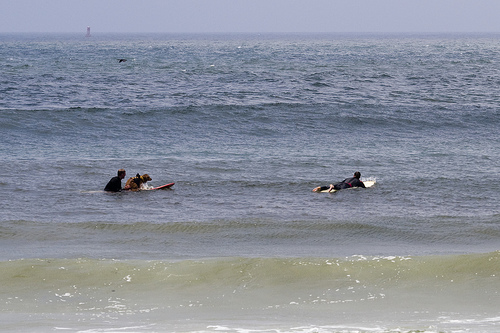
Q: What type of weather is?
A: It is cloudless.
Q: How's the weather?
A: It is cloudless.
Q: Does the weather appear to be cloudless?
A: Yes, it is cloudless.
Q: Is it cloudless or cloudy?
A: It is cloudless.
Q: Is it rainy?
A: No, it is cloudless.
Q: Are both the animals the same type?
A: No, they are birds and dogs.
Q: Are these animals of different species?
A: Yes, they are birds and dogs.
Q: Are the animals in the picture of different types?
A: Yes, they are birds and dogs.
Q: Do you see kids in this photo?
A: No, there are no kids.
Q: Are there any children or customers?
A: No, there are no children or customers.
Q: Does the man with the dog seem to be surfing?
A: Yes, the man is surfing.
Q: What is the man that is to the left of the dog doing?
A: The man is surfing.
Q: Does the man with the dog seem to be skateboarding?
A: No, the man is surfing.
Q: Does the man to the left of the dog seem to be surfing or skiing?
A: The man is surfing.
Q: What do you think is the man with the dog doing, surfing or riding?
A: The man is surfing.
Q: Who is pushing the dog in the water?
A: The man is pushing the dog.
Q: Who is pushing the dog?
A: The man is pushing the dog.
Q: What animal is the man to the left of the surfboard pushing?
A: The man is pushing the dog.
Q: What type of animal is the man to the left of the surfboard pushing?
A: The man is pushing the dog.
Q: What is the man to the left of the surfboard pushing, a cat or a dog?
A: The man is pushing a dog.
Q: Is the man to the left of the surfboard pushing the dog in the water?
A: Yes, the man is pushing the dog.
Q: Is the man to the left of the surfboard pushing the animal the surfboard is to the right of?
A: Yes, the man is pushing the dog.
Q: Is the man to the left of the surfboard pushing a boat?
A: No, the man is pushing the dog.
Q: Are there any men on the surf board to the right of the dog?
A: Yes, there is a man on the surfboard.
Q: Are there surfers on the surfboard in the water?
A: No, there is a man on the surfboard.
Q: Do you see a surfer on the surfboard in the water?
A: No, there is a man on the surfboard.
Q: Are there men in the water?
A: Yes, there is a man in the water.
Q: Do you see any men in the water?
A: Yes, there is a man in the water.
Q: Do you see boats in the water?
A: No, there is a man in the water.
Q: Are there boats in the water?
A: No, there is a man in the water.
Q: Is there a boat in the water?
A: No, there is a man in the water.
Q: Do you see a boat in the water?
A: No, there is a man in the water.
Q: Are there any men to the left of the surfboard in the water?
A: Yes, there is a man to the left of the surfboard.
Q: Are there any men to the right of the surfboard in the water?
A: No, the man is to the left of the surfboard.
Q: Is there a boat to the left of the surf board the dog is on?
A: No, there is a man to the left of the surfboard.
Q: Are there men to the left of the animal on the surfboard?
A: Yes, there is a man to the left of the dog.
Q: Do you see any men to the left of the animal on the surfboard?
A: Yes, there is a man to the left of the dog.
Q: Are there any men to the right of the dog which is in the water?
A: No, the man is to the left of the dog.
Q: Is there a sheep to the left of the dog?
A: No, there is a man to the left of the dog.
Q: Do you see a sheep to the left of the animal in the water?
A: No, there is a man to the left of the dog.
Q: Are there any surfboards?
A: Yes, there is a surfboard.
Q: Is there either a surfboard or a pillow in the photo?
A: Yes, there is a surfboard.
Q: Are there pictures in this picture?
A: No, there are no pictures.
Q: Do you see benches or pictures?
A: No, there are no pictures or benches.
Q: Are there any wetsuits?
A: Yes, there is a wetsuit.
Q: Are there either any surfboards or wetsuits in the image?
A: Yes, there is a wetsuit.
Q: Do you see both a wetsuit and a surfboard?
A: Yes, there are both a wetsuit and a surfboard.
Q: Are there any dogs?
A: Yes, there is a dog.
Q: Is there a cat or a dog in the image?
A: Yes, there is a dog.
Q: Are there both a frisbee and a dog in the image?
A: No, there is a dog but no frisbees.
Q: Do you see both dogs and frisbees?
A: No, there is a dog but no frisbees.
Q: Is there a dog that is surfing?
A: Yes, there is a dog that is surfing.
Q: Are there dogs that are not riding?
A: Yes, there is a dog that is surfing.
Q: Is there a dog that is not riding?
A: Yes, there is a dog that is surfing.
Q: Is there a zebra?
A: No, there are no zebras.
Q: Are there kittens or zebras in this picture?
A: No, there are no zebras or kittens.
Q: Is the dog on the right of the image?
A: No, the dog is on the left of the image.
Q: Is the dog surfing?
A: Yes, the dog is surfing.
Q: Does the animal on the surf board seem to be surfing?
A: Yes, the dog is surfing.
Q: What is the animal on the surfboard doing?
A: The dog is surfing.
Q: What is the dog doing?
A: The dog is surfing.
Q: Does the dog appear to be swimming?
A: No, the dog is surfing.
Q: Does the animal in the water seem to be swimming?
A: No, the dog is surfing.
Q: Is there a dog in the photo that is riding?
A: No, there is a dog but it is surfing.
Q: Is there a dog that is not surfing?
A: No, there is a dog but it is surfing.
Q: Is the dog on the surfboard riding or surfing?
A: The dog is surfing.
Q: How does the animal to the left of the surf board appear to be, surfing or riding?
A: The dog is surfing.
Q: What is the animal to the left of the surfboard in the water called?
A: The animal is a dog.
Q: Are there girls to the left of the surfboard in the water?
A: No, there is a dog to the left of the surfboard.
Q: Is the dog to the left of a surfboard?
A: Yes, the dog is to the left of a surfboard.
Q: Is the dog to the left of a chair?
A: No, the dog is to the left of a surfboard.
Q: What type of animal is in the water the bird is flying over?
A: The animal is a dog.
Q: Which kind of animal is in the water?
A: The animal is a dog.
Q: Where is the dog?
A: The dog is in the water.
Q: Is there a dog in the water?
A: Yes, there is a dog in the water.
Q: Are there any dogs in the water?
A: Yes, there is a dog in the water.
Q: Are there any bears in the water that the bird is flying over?
A: No, there is a dog in the water.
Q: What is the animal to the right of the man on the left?
A: The animal is a dog.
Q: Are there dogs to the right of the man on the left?
A: Yes, there is a dog to the right of the man.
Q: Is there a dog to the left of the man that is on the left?
A: No, the dog is to the right of the man.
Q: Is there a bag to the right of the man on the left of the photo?
A: No, there is a dog to the right of the man.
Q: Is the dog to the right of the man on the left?
A: Yes, the dog is to the right of the man.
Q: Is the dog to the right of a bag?
A: No, the dog is to the right of the man.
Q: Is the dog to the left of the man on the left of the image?
A: No, the dog is to the right of the man.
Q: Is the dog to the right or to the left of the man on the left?
A: The dog is to the right of the man.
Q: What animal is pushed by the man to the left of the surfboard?
A: The dog is pushed by the man.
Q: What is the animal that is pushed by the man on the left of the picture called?
A: The animal is a dog.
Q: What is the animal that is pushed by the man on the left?
A: The animal is a dog.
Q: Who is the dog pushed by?
A: The dog is pushed by the man.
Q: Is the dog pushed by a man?
A: Yes, the dog is pushed by a man.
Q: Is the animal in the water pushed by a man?
A: Yes, the dog is pushed by a man.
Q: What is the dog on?
A: The dog is on the surf board.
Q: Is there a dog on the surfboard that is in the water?
A: Yes, there is a dog on the surfboard.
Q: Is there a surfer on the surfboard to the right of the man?
A: No, there is a dog on the surfboard.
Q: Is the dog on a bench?
A: No, the dog is on a surfboard.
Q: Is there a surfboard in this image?
A: Yes, there is a surfboard.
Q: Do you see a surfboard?
A: Yes, there is a surfboard.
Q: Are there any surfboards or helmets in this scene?
A: Yes, there is a surfboard.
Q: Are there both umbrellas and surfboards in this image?
A: No, there is a surfboard but no umbrellas.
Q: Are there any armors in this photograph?
A: No, there are no armors.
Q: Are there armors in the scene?
A: No, there are no armors.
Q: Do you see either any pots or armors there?
A: No, there are no armors or pots.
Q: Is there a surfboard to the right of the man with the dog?
A: Yes, there is a surfboard to the right of the man.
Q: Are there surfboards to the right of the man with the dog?
A: Yes, there is a surfboard to the right of the man.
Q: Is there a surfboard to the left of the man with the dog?
A: No, the surfboard is to the right of the man.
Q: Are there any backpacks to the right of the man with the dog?
A: No, there is a surfboard to the right of the man.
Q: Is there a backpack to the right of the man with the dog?
A: No, there is a surfboard to the right of the man.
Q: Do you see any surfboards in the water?
A: Yes, there is a surfboard in the water.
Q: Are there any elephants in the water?
A: No, there is a surfboard in the water.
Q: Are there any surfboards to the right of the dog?
A: Yes, there is a surfboard to the right of the dog.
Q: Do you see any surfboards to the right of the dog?
A: Yes, there is a surfboard to the right of the dog.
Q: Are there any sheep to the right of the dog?
A: No, there is a surfboard to the right of the dog.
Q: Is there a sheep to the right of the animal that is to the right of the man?
A: No, there is a surfboard to the right of the dog.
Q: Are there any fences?
A: No, there are no fences.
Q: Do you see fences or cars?
A: No, there are no fences or cars.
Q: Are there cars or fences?
A: No, there are no fences or cars.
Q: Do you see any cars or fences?
A: No, there are no fences or cars.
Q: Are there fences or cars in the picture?
A: No, there are no fences or cars.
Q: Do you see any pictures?
A: No, there are no pictures.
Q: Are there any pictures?
A: No, there are no pictures.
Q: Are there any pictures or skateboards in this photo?
A: No, there are no pictures or skateboards.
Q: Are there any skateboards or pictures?
A: No, there are no pictures or skateboards.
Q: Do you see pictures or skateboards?
A: No, there are no pictures or skateboards.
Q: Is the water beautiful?
A: Yes, the water is beautiful.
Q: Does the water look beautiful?
A: Yes, the water is beautiful.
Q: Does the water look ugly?
A: No, the water is beautiful.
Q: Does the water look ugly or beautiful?
A: The water is beautiful.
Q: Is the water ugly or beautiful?
A: The water is beautiful.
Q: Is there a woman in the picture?
A: No, there are no women.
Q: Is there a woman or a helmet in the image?
A: No, there are no women or helmets.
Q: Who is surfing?
A: The man is surfing.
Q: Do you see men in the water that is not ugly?
A: Yes, there is a man in the water.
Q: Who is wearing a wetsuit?
A: The man is wearing a wetsuit.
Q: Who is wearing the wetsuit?
A: The man is wearing a wetsuit.